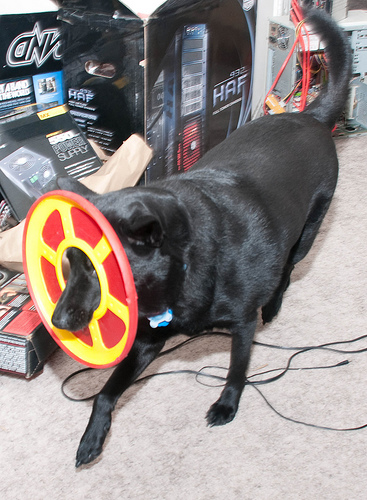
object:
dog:
[50, 2, 353, 467]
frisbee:
[20, 189, 138, 371]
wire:
[237, 323, 367, 433]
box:
[0, 273, 58, 381]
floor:
[10, 378, 52, 462]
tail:
[301, 0, 351, 126]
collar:
[182, 247, 190, 274]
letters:
[65, 154, 100, 181]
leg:
[203, 308, 258, 428]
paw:
[204, 396, 238, 428]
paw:
[75, 418, 113, 465]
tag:
[148, 307, 174, 330]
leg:
[72, 336, 160, 468]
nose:
[51, 313, 93, 333]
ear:
[120, 202, 163, 250]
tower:
[287, 0, 350, 55]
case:
[341, 11, 366, 133]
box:
[59, 0, 262, 188]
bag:
[78, 130, 151, 195]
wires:
[302, 32, 307, 109]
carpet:
[328, 199, 364, 305]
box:
[265, 18, 297, 113]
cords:
[303, 26, 311, 108]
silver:
[148, 311, 173, 329]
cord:
[264, 33, 298, 114]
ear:
[56, 177, 96, 198]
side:
[134, 184, 339, 312]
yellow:
[31, 218, 40, 274]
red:
[77, 214, 99, 237]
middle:
[61, 247, 103, 313]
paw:
[260, 301, 279, 326]